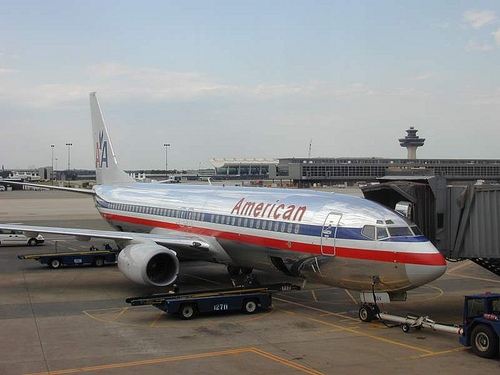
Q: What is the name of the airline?
A: American Airlines.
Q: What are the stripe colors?
A: Red, white and blue.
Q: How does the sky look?
A: Partly cloudy.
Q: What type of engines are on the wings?
A: Turbines.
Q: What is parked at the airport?
A: An airplane.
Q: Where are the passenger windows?
A: On the jet.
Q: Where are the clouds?
A: In the sky.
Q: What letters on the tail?
A: AA.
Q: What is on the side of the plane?
A: Windows.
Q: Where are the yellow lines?
A: On the runway.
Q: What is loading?
A: The plane.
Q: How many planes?
A: 1.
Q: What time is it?
A: Day time.